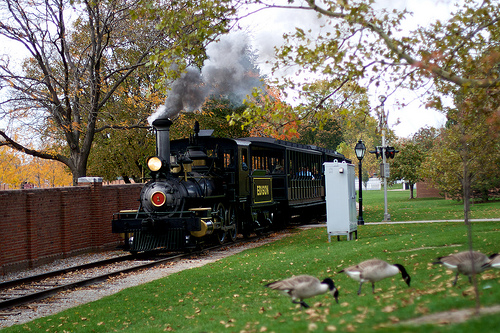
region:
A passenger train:
[88, 82, 375, 252]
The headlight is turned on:
[131, 145, 176, 173]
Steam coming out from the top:
[146, 51, 249, 131]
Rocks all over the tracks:
[11, 243, 144, 299]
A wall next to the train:
[13, 178, 115, 252]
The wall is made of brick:
[19, 185, 111, 249]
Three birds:
[262, 233, 494, 301]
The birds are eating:
[245, 220, 499, 330]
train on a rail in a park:
[125, 31, 347, 258]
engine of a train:
[105, 109, 275, 266]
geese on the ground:
[260, 238, 499, 315]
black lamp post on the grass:
[356, 129, 368, 221]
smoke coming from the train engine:
[148, 14, 313, 115]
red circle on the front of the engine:
[149, 191, 166, 206]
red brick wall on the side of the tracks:
[0, 183, 154, 263]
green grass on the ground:
[19, 185, 497, 330]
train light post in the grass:
[371, 103, 401, 224]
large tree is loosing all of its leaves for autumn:
[2, 2, 185, 177]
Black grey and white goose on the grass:
[262, 251, 349, 316]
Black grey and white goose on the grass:
[335, 258, 415, 296]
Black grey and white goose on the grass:
[437, 234, 494, 283]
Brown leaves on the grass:
[79, 312, 113, 326]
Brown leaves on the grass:
[122, 293, 169, 330]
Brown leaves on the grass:
[174, 273, 217, 310]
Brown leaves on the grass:
[218, 308, 277, 332]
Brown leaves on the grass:
[293, 308, 350, 330]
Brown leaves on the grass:
[343, 293, 400, 329]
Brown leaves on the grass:
[395, 283, 449, 309]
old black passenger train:
[112, 118, 354, 260]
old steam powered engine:
[109, 115, 276, 260]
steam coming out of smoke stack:
[146, 31, 258, 161]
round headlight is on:
[145, 155, 162, 172]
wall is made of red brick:
[0, 173, 155, 273]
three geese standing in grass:
[263, 248, 498, 313]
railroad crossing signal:
[368, 95, 400, 224]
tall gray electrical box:
[320, 158, 360, 244]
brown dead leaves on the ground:
[3, 198, 497, 331]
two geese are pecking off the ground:
[262, 247, 412, 308]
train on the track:
[80, 56, 356, 268]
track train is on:
[6, 275, 126, 288]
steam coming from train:
[142, 36, 285, 122]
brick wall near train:
[3, 178, 176, 262]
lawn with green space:
[258, 239, 484, 314]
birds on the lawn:
[268, 253, 488, 315]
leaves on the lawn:
[315, 309, 373, 322]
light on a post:
[351, 140, 370, 230]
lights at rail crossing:
[373, 139, 401, 159]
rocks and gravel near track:
[126, 274, 144, 281]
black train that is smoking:
[100, 83, 375, 270]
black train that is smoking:
[100, 90, 370, 279]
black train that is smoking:
[92, 48, 369, 271]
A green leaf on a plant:
[462, 140, 465, 144]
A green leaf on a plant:
[436, 157, 440, 159]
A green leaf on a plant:
[468, 122, 477, 126]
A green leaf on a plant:
[460, 112, 464, 117]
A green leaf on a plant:
[477, 82, 482, 85]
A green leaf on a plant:
[474, 138, 477, 140]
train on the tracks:
[46, 80, 427, 294]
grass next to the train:
[177, 260, 264, 323]